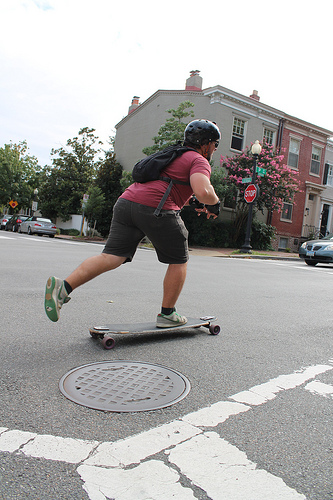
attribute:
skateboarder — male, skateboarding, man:
[45, 118, 221, 330]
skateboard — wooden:
[90, 314, 225, 349]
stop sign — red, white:
[242, 183, 257, 202]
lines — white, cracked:
[4, 357, 330, 496]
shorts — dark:
[101, 190, 190, 265]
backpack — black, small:
[135, 141, 206, 187]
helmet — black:
[182, 117, 222, 146]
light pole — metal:
[239, 154, 258, 257]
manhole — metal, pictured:
[58, 361, 190, 414]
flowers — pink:
[219, 136, 298, 214]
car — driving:
[294, 229, 332, 265]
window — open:
[228, 113, 247, 155]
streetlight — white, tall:
[250, 141, 262, 157]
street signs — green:
[239, 163, 268, 183]